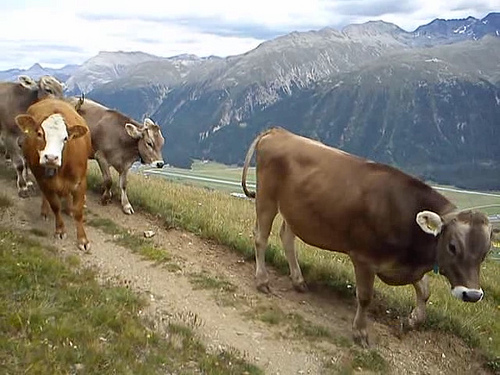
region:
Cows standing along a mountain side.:
[1, 3, 496, 357]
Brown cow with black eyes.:
[234, 111, 498, 343]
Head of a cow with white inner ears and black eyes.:
[414, 203, 499, 310]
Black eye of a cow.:
[438, 236, 468, 266]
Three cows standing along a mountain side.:
[0, 66, 188, 243]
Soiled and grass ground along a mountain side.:
[9, 153, 237, 338]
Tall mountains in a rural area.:
[66, 0, 493, 177]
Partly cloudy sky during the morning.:
[6, 2, 498, 60]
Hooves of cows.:
[31, 177, 165, 262]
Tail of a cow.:
[228, 114, 299, 205]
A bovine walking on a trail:
[238, 127, 496, 349]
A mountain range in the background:
[0, 13, 499, 190]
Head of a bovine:
[416, 208, 498, 304]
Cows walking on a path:
[0, 74, 166, 255]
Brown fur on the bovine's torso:
[286, 163, 398, 237]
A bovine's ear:
[415, 210, 444, 236]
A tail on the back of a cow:
[236, 133, 258, 201]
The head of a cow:
[13, 113, 90, 168]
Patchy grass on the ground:
[1, 227, 242, 369]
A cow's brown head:
[125, 118, 165, 171]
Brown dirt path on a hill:
[32, 194, 379, 369]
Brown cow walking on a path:
[236, 118, 499, 354]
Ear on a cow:
[414, 201, 444, 244]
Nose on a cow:
[433, 242, 497, 309]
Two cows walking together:
[10, 93, 182, 258]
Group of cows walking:
[6, 85, 173, 247]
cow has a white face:
[35, 113, 69, 164]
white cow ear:
[417, 211, 443, 233]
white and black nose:
[453, 286, 484, 301]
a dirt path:
[11, 175, 440, 370]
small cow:
[73, 97, 164, 213]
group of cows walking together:
[3, 75, 492, 328]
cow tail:
[238, 129, 274, 197]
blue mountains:
[6, 11, 496, 185]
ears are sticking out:
[13, 112, 87, 139]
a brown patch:
[33, 123, 47, 150]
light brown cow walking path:
[226, 113, 498, 306]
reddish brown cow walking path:
[14, 93, 98, 245]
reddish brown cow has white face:
[32, 106, 72, 175]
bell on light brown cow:
[425, 250, 447, 280]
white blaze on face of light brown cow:
[444, 282, 488, 303]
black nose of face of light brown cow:
[461, 289, 483, 302]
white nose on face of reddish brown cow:
[43, 151, 61, 163]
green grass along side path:
[17, 263, 102, 357]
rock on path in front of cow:
[134, 223, 164, 241]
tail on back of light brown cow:
[231, 128, 268, 206]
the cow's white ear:
[414, 211, 446, 236]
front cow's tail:
[238, 135, 256, 201]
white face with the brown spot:
[21, 108, 74, 170]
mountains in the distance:
[176, 55, 478, 143]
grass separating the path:
[119, 228, 181, 272]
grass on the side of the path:
[16, 266, 100, 334]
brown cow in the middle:
[16, 95, 100, 254]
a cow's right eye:
[447, 243, 458, 256]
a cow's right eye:
[35, 129, 42, 139]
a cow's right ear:
[415, 210, 445, 237]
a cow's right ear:
[15, 113, 35, 132]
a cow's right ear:
[126, 124, 144, 137]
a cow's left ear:
[66, 123, 86, 138]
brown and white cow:
[240, 125, 486, 335]